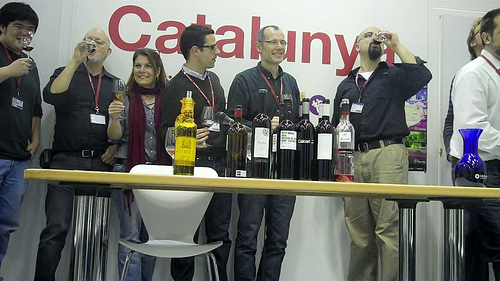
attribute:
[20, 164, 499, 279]
table — full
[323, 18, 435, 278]
man — drinking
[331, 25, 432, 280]
man — drinking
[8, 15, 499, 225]
people — tasting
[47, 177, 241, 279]
chair — white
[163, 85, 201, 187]
bottle — yellow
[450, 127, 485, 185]
vase — blue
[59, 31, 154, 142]
man — drinking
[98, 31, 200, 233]
woman — holding up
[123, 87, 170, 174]
scarf — burgundy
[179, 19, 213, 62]
hair — black